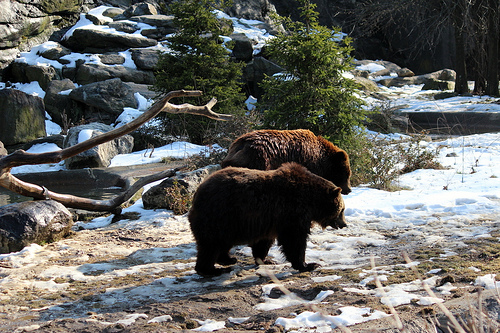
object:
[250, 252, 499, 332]
grass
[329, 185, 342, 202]
ear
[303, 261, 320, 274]
paw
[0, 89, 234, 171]
tree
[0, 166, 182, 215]
tree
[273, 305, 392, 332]
snow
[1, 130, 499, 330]
ground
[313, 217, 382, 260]
ripples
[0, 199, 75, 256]
large rock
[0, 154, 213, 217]
fallen tree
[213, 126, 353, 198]
bear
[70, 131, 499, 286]
snow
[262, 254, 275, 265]
paw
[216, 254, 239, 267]
paw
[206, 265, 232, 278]
paw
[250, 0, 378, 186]
tree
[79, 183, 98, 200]
ripples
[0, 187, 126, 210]
river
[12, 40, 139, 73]
snow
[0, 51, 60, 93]
rock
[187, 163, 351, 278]
bear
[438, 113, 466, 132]
ripples